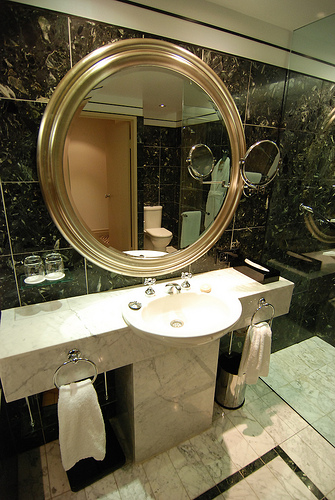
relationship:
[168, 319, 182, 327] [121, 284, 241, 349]
drain in sink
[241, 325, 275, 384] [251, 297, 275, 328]
towel on hanger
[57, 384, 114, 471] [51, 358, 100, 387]
towel on rack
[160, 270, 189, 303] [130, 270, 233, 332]
faucet on sink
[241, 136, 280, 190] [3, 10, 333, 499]
mirror in bathroom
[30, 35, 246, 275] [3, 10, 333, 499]
mirror in bathroom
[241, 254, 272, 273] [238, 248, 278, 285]
tissues in box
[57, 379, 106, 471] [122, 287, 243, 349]
towel near basin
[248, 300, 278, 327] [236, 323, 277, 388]
hanger for towel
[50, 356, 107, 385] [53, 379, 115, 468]
hanger for towel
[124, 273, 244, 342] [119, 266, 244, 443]
basin of sink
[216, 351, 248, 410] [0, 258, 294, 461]
trash bin under sink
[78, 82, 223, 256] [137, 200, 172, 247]
reflection of toilet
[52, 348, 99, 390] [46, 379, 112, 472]
hanger for towel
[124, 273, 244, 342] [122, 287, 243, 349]
basin of basin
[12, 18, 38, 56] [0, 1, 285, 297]
marble on wall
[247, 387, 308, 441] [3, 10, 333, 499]
floor in bathroom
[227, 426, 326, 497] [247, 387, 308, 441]
tile on floor